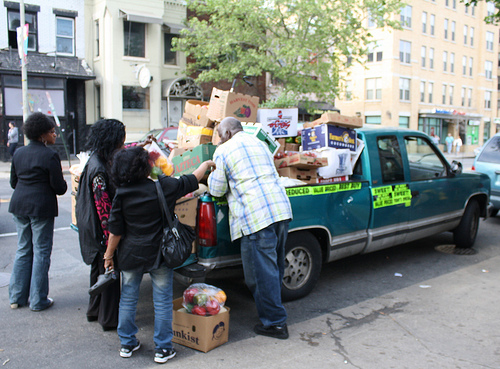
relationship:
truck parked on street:
[70, 127, 491, 298] [1, 175, 499, 367]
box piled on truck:
[207, 86, 261, 120] [70, 127, 491, 298]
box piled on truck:
[258, 106, 302, 139] [70, 127, 491, 298]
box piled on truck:
[307, 111, 364, 131] [70, 127, 491, 298]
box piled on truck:
[297, 120, 360, 154] [70, 127, 491, 298]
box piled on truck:
[274, 151, 331, 172] [70, 127, 491, 298]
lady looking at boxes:
[6, 110, 68, 314] [141, 85, 363, 183]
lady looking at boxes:
[73, 114, 125, 331] [141, 85, 363, 183]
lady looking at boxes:
[101, 144, 216, 365] [141, 85, 363, 183]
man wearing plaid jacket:
[206, 115, 296, 342] [202, 130, 294, 242]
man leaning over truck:
[206, 115, 296, 342] [70, 127, 491, 298]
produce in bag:
[187, 287, 218, 312] [183, 284, 226, 315]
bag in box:
[183, 284, 226, 315] [171, 295, 230, 352]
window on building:
[398, 3, 413, 31] [334, 1, 499, 153]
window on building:
[398, 38, 412, 65] [334, 1, 499, 153]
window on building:
[397, 75, 414, 105] [334, 1, 499, 153]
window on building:
[361, 71, 385, 104] [334, 1, 499, 153]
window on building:
[418, 77, 434, 102] [334, 1, 499, 153]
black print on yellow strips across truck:
[284, 180, 349, 204] [178, 147, 464, 298]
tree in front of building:
[184, 55, 353, 114] [283, 99, 383, 110]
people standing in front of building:
[437, 132, 467, 180] [387, 99, 434, 135]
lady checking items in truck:
[0, 70, 62, 359] [171, 109, 304, 194]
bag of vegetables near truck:
[180, 281, 227, 316] [207, 221, 326, 286]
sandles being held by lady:
[63, 254, 116, 322] [101, 144, 216, 365]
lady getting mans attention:
[110, 141, 214, 368] [179, 132, 204, 172]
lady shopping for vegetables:
[71, 114, 118, 330] [158, 120, 207, 185]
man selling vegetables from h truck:
[210, 125, 304, 334] [182, 158, 439, 333]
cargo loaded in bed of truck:
[167, 116, 278, 165] [100, 67, 444, 224]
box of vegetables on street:
[157, 297, 232, 355] [164, 333, 396, 369]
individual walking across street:
[2, 116, 16, 190] [2, 126, 88, 218]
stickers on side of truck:
[362, 179, 427, 211] [234, 114, 484, 369]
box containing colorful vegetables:
[157, 254, 250, 369] [191, 290, 223, 339]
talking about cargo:
[14, 84, 289, 237] [143, 164, 194, 186]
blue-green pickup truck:
[362, 198, 398, 216] [135, 112, 489, 354]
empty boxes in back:
[104, 85, 341, 208] [187, 190, 279, 229]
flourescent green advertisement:
[318, 161, 448, 223] [362, 196, 415, 207]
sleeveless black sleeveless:
[72, 156, 109, 304] [72, 154, 117, 266]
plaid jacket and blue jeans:
[199, 140, 300, 237] [255, 226, 295, 299]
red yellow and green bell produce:
[202, 303, 222, 312] [189, 293, 209, 309]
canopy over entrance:
[147, 76, 209, 112] [93, 102, 206, 173]